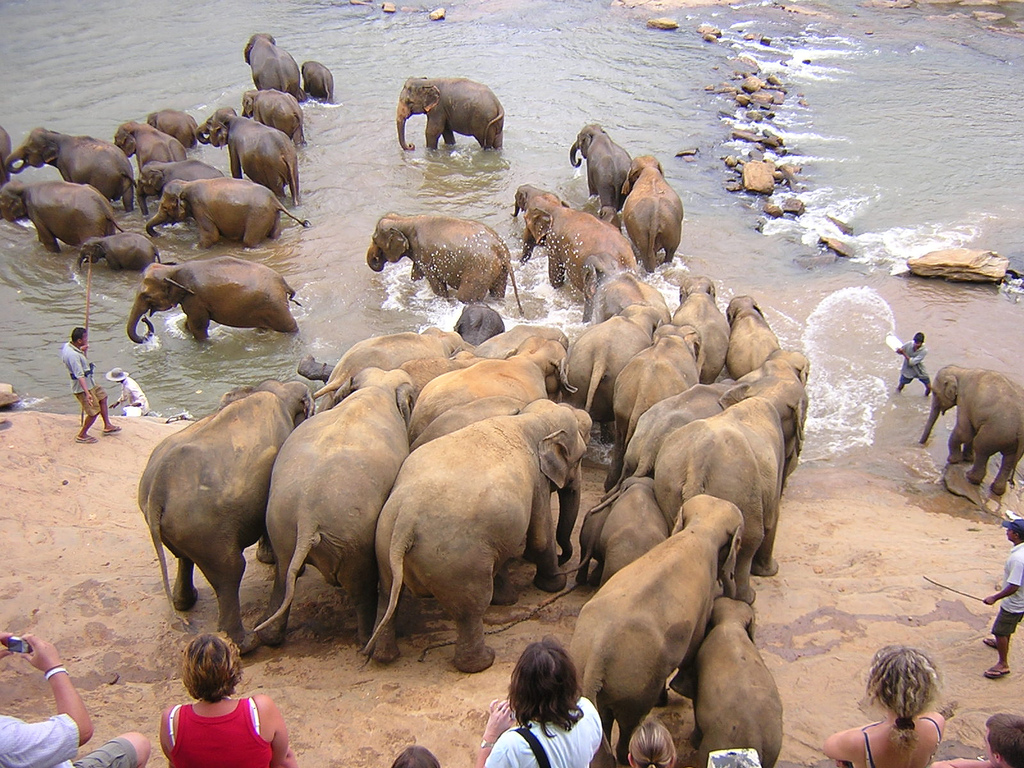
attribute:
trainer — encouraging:
[859, 331, 944, 437]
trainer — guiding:
[956, 515, 1015, 624]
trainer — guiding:
[63, 324, 163, 469]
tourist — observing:
[124, 633, 276, 765]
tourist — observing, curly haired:
[815, 633, 950, 761]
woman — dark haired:
[498, 631, 602, 727]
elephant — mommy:
[225, 28, 396, 119]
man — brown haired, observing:
[938, 703, 1018, 764]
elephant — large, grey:
[23, 145, 179, 306]